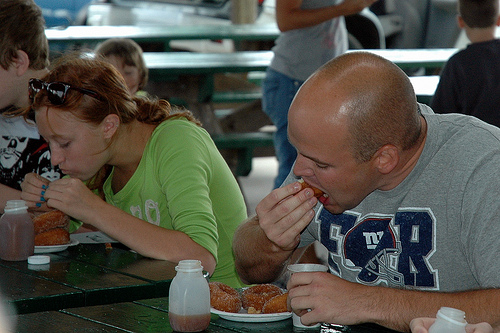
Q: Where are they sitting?
A: At picnic tables.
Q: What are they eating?
A: Donuts.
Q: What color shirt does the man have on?
A: Gray.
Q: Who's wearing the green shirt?
A: The woman.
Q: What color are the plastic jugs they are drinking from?
A: White.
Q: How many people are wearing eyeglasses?
A: None.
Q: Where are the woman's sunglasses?
A: On her head.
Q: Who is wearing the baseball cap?
A: Nobody.